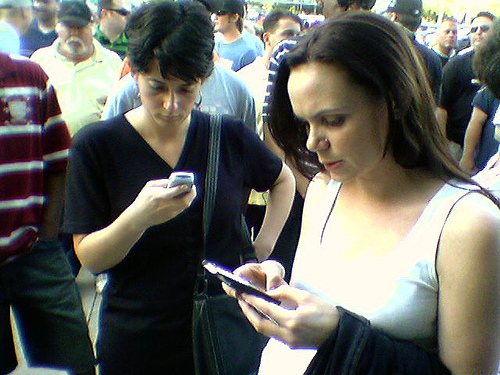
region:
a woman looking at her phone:
[220, 11, 498, 373]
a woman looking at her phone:
[61, 0, 295, 374]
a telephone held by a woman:
[165, 171, 194, 191]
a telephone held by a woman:
[200, 258, 281, 305]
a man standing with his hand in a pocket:
[0, 50, 96, 374]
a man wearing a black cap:
[29, 0, 121, 137]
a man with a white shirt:
[235, 7, 305, 141]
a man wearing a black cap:
[378, 0, 442, 107]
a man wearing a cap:
[0, 0, 47, 54]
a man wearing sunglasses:
[90, 0, 129, 62]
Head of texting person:
[286, 11, 433, 187]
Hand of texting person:
[236, 284, 332, 351]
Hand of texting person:
[221, 258, 284, 283]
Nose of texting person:
[303, 124, 328, 154]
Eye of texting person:
[316, 112, 353, 129]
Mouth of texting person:
[317, 159, 346, 170]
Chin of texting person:
[326, 169, 359, 185]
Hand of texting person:
[136, 174, 199, 226]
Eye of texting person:
[146, 81, 163, 93]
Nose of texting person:
[159, 89, 181, 114]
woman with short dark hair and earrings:
[106, 3, 223, 145]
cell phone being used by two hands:
[190, 245, 330, 355]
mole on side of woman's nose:
[315, 133, 335, 149]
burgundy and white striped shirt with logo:
[1, 56, 81, 279]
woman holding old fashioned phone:
[130, 159, 209, 236]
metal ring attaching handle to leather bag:
[178, 264, 216, 323]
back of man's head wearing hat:
[378, 2, 428, 37]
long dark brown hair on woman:
[268, 12, 497, 214]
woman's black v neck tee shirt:
[45, 98, 290, 300]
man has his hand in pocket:
[23, 213, 69, 275]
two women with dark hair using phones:
[81, 2, 495, 364]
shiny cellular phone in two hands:
[198, 246, 318, 354]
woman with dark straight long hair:
[252, 12, 496, 247]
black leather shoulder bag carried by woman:
[193, 97, 300, 373]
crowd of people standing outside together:
[20, 8, 482, 371]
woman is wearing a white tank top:
[273, 160, 485, 334]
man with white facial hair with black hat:
[44, 1, 108, 68]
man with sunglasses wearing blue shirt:
[208, 0, 265, 61]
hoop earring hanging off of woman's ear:
[188, 86, 210, 114]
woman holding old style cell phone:
[133, 155, 203, 234]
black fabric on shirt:
[152, 255, 179, 282]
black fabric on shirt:
[175, 235, 195, 265]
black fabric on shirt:
[89, 158, 111, 180]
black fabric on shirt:
[117, 159, 138, 162]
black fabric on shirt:
[230, 161, 245, 173]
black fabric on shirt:
[220, 147, 255, 182]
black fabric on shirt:
[18, 146, 34, 171]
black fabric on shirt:
[87, 139, 121, 159]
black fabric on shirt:
[113, 311, 143, 332]